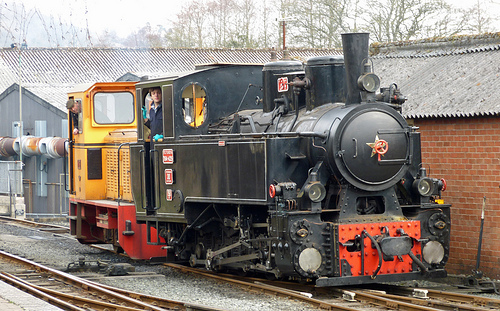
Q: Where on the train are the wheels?
A: Bottom.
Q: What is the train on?
A: Train tracks.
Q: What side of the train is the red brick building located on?
A: Left.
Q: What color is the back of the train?
A: Yellow.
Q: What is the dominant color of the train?
A: Black.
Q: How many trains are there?
A: 1.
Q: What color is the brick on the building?
A: Red.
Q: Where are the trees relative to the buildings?
A: Behind.